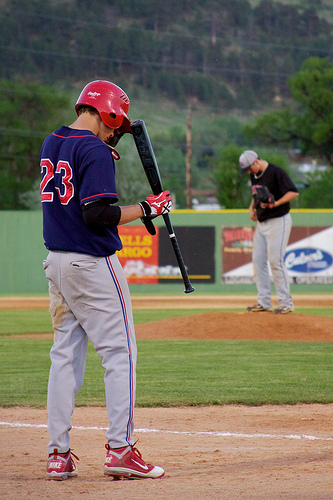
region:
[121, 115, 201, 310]
the bat is black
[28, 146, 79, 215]
jersey number is 23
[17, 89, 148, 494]
this is a person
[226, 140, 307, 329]
this is a person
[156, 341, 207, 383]
a patch of grass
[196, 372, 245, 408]
a patch of grass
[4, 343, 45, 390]
a patch of grass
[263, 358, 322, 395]
a patch of grass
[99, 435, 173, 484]
this is a shoe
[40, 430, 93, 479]
this is a shoe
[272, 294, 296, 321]
this is a shoe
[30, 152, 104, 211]
red number on back of uniform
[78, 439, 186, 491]
red nike cleats on players feet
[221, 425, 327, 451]
white line painted on ground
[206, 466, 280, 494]
light brown area of dirt on ground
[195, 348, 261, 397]
green patch of grass on ground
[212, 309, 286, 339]
light brown area of dirt on the pitchers mound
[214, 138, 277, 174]
baseball player in cap looking down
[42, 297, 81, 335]
small area of dirt on back of player's pants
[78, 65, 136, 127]
red helmet on top of batter's head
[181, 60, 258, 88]
silver metal wire in the air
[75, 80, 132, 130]
the helmet is red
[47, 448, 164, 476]
a couple of red sneakers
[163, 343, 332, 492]
the baseball field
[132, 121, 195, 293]
a black baseball bat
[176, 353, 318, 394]
green grass in the field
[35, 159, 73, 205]
the nummber 23 in red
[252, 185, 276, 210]
the glove of the baseball player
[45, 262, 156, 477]
the two legs of the player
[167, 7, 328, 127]
the background is out of focus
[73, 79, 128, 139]
the head of the player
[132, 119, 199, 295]
a long black bat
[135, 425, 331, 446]
a long white line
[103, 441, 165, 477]
a man's red and white shoe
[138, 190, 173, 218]
a red and white glove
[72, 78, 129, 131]
a red helmet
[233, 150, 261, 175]
a gray baseball cap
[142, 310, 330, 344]
part of a pitcher's mound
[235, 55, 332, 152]
part of a large green tree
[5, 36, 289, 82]
a long electrical power line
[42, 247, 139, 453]
gray uniform pants